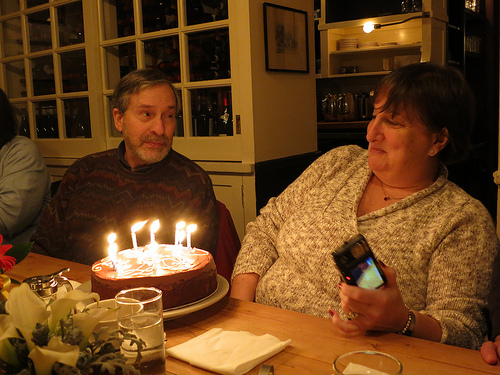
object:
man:
[230, 62, 498, 347]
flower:
[0, 235, 17, 274]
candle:
[177, 244, 183, 253]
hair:
[374, 63, 500, 221]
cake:
[89, 243, 215, 310]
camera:
[331, 234, 387, 291]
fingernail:
[329, 309, 334, 316]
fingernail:
[338, 283, 342, 288]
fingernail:
[378, 259, 387, 267]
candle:
[132, 232, 138, 248]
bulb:
[363, 20, 376, 33]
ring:
[347, 311, 359, 321]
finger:
[328, 260, 397, 338]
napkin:
[166, 328, 292, 375]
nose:
[366, 120, 386, 142]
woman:
[230, 63, 498, 349]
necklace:
[383, 181, 405, 201]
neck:
[371, 165, 440, 196]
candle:
[174, 230, 179, 245]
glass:
[330, 350, 402, 374]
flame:
[131, 219, 149, 232]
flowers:
[2, 282, 99, 329]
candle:
[187, 233, 192, 251]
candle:
[150, 234, 155, 245]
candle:
[108, 242, 117, 261]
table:
[5, 249, 500, 375]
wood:
[171, 299, 499, 375]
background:
[314, 1, 442, 143]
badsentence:
[330, 260, 403, 333]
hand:
[328, 259, 409, 334]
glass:
[115, 287, 165, 373]